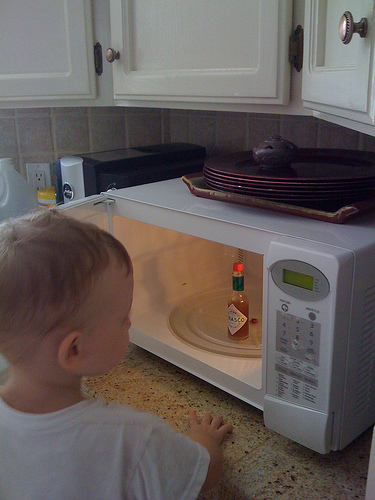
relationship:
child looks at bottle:
[1, 207, 236, 498] [223, 259, 251, 344]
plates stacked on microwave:
[201, 143, 373, 205] [98, 176, 371, 453]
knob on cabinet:
[338, 9, 368, 46] [7, 0, 358, 123]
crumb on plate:
[250, 318, 258, 324] [164, 275, 265, 350]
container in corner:
[26, 179, 68, 215] [8, 114, 243, 215]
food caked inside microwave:
[177, 278, 190, 287] [90, 183, 349, 435]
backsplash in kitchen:
[2, 107, 374, 214] [2, 0, 373, 495]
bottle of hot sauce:
[227, 261, 249, 341] [228, 301, 250, 339]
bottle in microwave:
[227, 261, 249, 341] [0, 175, 373, 454]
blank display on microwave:
[283, 269, 313, 291] [71, 172, 374, 460]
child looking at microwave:
[1, 207, 236, 498] [38, 132, 372, 481]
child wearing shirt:
[1, 207, 236, 498] [0, 395, 210, 497]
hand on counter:
[184, 409, 232, 441] [150, 370, 311, 484]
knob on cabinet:
[338, 9, 368, 46] [297, 0, 374, 122]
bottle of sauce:
[223, 259, 251, 344] [228, 298, 247, 338]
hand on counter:
[175, 403, 236, 448] [114, 354, 372, 498]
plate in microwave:
[169, 281, 263, 360] [0, 175, 373, 454]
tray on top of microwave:
[0, 176, 372, 457] [183, 170, 374, 225]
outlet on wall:
[26, 161, 51, 192] [2, 111, 373, 213]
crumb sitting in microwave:
[248, 316, 259, 323] [71, 172, 374, 460]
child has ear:
[1, 207, 236, 498] [55, 328, 82, 377]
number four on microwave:
[279, 318, 288, 331] [0, 175, 373, 454]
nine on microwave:
[307, 337, 315, 346] [71, 172, 374, 460]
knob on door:
[330, 9, 361, 49] [298, 0, 374, 128]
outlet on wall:
[22, 158, 56, 197] [2, 111, 373, 213]